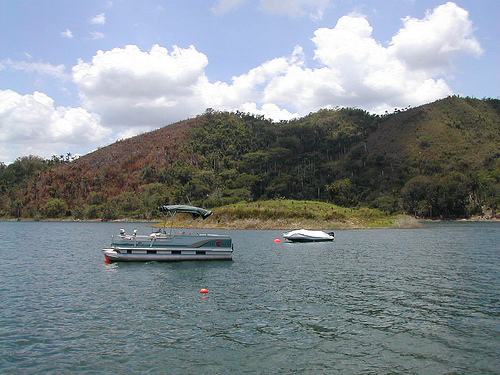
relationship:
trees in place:
[164, 116, 354, 214] [174, 115, 446, 240]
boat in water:
[63, 167, 255, 292] [255, 274, 399, 345]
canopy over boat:
[156, 205, 233, 231] [63, 167, 255, 292]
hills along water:
[20, 98, 283, 203] [225, 245, 342, 343]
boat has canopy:
[63, 167, 255, 292] [156, 205, 233, 231]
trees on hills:
[164, 116, 354, 214] [20, 98, 283, 203]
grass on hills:
[90, 122, 214, 235] [20, 98, 283, 203]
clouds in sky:
[67, 40, 257, 132] [199, 6, 240, 43]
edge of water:
[73, 265, 107, 290] [255, 274, 399, 345]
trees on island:
[164, 116, 354, 214] [22, 68, 490, 319]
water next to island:
[255, 274, 399, 345] [22, 68, 490, 319]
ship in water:
[63, 167, 255, 292] [255, 274, 399, 345]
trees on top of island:
[164, 116, 354, 214] [22, 68, 490, 319]